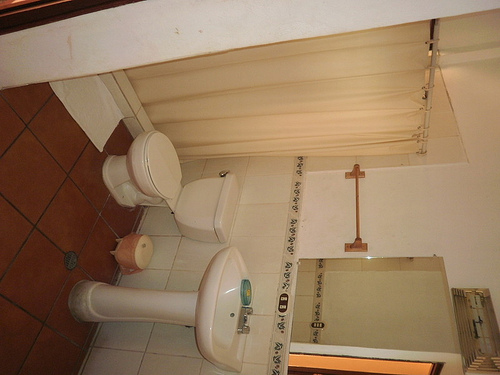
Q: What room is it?
A: Bathroom.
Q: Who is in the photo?
A: No people.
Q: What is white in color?
A: The toilet.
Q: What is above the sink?
A: Mirror.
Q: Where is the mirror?
A: Above the sink.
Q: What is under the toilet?
A: The tile.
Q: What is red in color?
A: The tile.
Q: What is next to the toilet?
A: Curtain.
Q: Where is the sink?
A: Next to toilet.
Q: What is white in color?
A: The sink.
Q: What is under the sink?
A: The floor.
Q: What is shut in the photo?
A: The toilet.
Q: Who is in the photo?
A: No people.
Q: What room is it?
A: Bathroom.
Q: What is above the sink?
A: Mirror.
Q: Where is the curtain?
A: Next to toilet.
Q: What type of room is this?
A: Bathroom.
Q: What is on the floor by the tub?
A: Floor mat.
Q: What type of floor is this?
A: Tile.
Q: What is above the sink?
A: A mirror.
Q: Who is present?
A: No one.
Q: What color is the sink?
A: White.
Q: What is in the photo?
A: Toilet.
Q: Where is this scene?
A: Inside a bathroom.